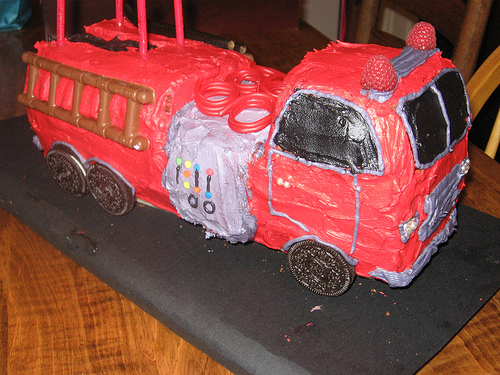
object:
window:
[277, 97, 377, 172]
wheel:
[287, 240, 351, 297]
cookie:
[286, 240, 359, 297]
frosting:
[15, 14, 472, 297]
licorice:
[194, 66, 283, 133]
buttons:
[174, 157, 215, 198]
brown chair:
[353, 0, 381, 43]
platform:
[1, 115, 499, 368]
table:
[1, 2, 499, 374]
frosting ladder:
[12, 53, 153, 153]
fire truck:
[16, 18, 470, 298]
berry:
[360, 57, 398, 93]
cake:
[12, 17, 470, 297]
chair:
[466, 47, 498, 157]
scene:
[0, 21, 498, 361]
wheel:
[82, 158, 134, 216]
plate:
[0, 167, 495, 359]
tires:
[44, 144, 92, 196]